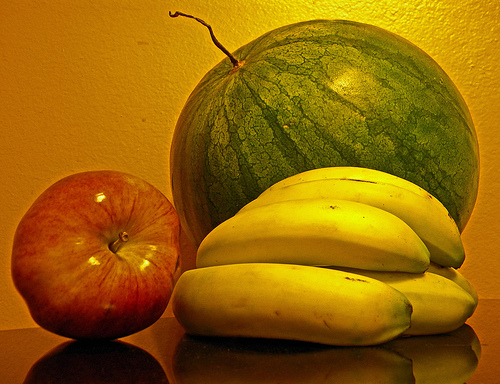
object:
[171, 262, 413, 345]
banana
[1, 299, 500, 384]
table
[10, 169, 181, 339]
apple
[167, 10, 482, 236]
watermelon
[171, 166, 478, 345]
bananas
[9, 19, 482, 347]
fruit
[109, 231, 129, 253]
stem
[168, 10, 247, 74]
stem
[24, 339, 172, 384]
reflection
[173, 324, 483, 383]
reflection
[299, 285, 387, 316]
skin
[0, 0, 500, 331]
wall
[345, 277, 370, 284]
spot